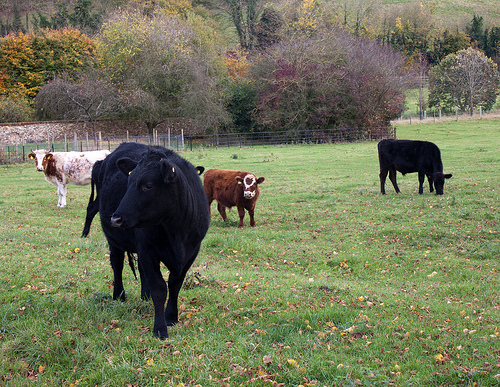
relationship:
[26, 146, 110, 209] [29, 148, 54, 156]
cow has horns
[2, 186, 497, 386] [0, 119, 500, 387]
leaves on field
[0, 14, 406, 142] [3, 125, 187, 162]
trees along fence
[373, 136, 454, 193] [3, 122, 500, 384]
cow eating grass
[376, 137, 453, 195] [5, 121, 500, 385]
cow in field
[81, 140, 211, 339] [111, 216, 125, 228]
cow has nose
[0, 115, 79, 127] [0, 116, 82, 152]
train track on hill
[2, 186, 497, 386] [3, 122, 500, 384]
leaves in grass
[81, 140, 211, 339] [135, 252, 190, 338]
cow has legs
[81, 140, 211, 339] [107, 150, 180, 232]
cow has head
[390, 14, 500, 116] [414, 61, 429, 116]
trees has trunk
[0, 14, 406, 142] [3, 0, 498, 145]
trees in background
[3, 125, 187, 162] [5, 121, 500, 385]
fence in field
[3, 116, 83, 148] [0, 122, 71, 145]
wall of stone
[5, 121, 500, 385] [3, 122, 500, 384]
field has grass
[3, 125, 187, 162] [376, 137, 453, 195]
fence behind cow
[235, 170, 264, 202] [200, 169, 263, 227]
head of cow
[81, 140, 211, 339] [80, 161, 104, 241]
cow has tail